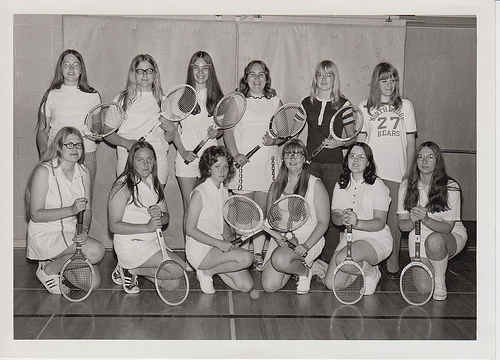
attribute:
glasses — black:
[134, 66, 155, 75]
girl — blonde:
[98, 51, 180, 197]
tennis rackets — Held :
[398, 211, 436, 306]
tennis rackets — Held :
[331, 205, 368, 305]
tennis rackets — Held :
[223, 191, 310, 260]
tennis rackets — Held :
[304, 101, 361, 161]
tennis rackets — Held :
[183, 90, 245, 165]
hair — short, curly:
[194, 144, 234, 183]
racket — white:
[390, 244, 446, 304]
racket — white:
[326, 251, 371, 309]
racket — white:
[161, 82, 196, 115]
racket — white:
[53, 243, 97, 295]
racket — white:
[140, 252, 201, 309]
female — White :
[105, 141, 185, 293]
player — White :
[176, 147, 265, 272]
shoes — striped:
[33, 252, 146, 303]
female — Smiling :
[394, 139, 469, 305]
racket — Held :
[82, 97, 120, 146]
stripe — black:
[14, 310, 478, 324]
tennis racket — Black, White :
[329, 205, 369, 308]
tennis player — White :
[222, 53, 289, 200]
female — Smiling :
[186, 146, 256, 293]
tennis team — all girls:
[25, 47, 467, 304]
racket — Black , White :
[76, 100, 129, 138]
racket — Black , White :
[128, 85, 199, 146]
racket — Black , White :
[181, 90, 249, 163]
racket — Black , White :
[234, 103, 306, 170]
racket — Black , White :
[300, 105, 366, 162]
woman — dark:
[397, 127, 462, 294]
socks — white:
[424, 251, 451, 288]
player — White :
[27, 134, 117, 309]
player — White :
[110, 139, 196, 301]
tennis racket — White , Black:
[147, 205, 192, 307]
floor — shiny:
[11, 219, 470, 341]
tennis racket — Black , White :
[230, 194, 311, 245]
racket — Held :
[58, 197, 98, 309]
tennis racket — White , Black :
[186, 92, 246, 167]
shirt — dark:
[263, 62, 385, 216]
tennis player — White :
[395, 142, 468, 298]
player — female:
[282, 60, 359, 178]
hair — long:
[401, 136, 451, 224]